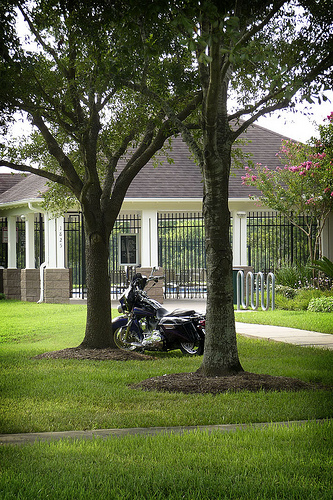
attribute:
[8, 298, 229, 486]
grass — green, loose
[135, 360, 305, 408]
mound — dirt, large, mulch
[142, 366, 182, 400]
paper — white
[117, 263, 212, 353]
motorcycle — parked, purple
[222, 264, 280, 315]
railing — silver, bike rack, grey, metal, squiggly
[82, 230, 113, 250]
cross — small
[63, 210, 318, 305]
bars — iron, metal, black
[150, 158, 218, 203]
shingles — grey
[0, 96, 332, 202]
roof — grey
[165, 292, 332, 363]
concrete — grey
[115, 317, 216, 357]
tires — round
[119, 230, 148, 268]
plaque — black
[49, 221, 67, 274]
beam — white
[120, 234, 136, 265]
writing — white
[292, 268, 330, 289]
flowers — light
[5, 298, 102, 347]
sun — shining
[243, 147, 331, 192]
flowers — pink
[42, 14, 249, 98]
leaves — green